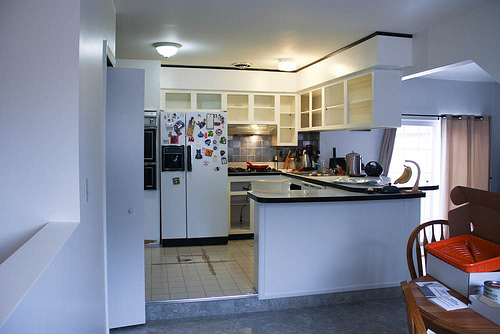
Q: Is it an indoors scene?
A: Yes, it is indoors.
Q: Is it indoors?
A: Yes, it is indoors.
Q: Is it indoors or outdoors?
A: It is indoors.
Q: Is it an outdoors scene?
A: No, it is indoors.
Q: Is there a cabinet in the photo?
A: Yes, there is a cabinet.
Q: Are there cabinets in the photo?
A: Yes, there is a cabinet.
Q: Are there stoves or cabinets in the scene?
A: Yes, there is a cabinet.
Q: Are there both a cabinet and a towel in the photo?
A: No, there is a cabinet but no towels.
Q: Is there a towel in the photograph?
A: No, there are no towels.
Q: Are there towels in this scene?
A: No, there are no towels.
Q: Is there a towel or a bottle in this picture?
A: No, there are no towels or bottles.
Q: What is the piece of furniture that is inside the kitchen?
A: The piece of furniture is a cabinet.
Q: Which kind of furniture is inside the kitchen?
A: The piece of furniture is a cabinet.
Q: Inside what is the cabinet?
A: The cabinet is inside the kitchen.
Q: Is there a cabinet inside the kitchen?
A: Yes, there is a cabinet inside the kitchen.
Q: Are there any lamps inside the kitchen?
A: No, there is a cabinet inside the kitchen.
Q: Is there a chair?
A: Yes, there is a chair.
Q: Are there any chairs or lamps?
A: Yes, there is a chair.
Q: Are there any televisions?
A: No, there are no televisions.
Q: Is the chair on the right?
A: Yes, the chair is on the right of the image.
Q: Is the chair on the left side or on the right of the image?
A: The chair is on the right of the image.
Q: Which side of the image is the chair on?
A: The chair is on the right of the image.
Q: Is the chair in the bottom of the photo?
A: Yes, the chair is in the bottom of the image.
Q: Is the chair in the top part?
A: No, the chair is in the bottom of the image.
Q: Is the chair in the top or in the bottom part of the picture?
A: The chair is in the bottom of the image.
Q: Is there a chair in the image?
A: Yes, there is a chair.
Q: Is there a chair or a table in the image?
A: Yes, there is a chair.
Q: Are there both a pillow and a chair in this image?
A: No, there is a chair but no pillows.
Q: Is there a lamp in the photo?
A: No, there are no lamps.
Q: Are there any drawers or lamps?
A: No, there are no lamps or drawers.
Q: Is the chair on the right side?
A: Yes, the chair is on the right of the image.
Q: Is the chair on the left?
A: No, the chair is on the right of the image.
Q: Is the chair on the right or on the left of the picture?
A: The chair is on the right of the image.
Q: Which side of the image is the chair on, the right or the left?
A: The chair is on the right of the image.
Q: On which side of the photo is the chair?
A: The chair is on the right of the image.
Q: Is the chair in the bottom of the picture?
A: Yes, the chair is in the bottom of the image.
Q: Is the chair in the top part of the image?
A: No, the chair is in the bottom of the image.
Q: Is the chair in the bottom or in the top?
A: The chair is in the bottom of the image.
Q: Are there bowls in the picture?
A: No, there are no bowls.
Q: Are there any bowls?
A: No, there are no bowls.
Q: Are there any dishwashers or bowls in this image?
A: No, there are no bowls or dishwashers.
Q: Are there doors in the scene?
A: Yes, there is a door.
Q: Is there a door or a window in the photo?
A: Yes, there is a door.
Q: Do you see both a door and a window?
A: Yes, there are both a door and a window.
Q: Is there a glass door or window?
A: Yes, there is a glass door.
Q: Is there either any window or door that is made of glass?
A: Yes, the door is made of glass.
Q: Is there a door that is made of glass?
A: Yes, there is a door that is made of glass.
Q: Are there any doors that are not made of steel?
A: Yes, there is a door that is made of glass.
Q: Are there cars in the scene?
A: No, there are no cars.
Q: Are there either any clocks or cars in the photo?
A: No, there are no cars or clocks.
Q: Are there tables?
A: Yes, there is a table.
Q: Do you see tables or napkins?
A: Yes, there is a table.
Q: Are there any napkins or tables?
A: Yes, there is a table.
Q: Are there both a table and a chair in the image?
A: Yes, there are both a table and a chair.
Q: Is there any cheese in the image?
A: No, there is no cheese.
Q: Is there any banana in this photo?
A: Yes, there are bananas.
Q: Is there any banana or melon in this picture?
A: Yes, there are bananas.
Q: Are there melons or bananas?
A: Yes, there are bananas.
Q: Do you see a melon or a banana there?
A: Yes, there are bananas.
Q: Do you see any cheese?
A: No, there is no cheese.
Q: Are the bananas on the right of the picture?
A: Yes, the bananas are on the right of the image.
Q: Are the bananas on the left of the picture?
A: No, the bananas are on the right of the image.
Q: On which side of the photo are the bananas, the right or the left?
A: The bananas are on the right of the image.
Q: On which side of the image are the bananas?
A: The bananas are on the right of the image.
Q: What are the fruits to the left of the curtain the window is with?
A: The fruits are bananas.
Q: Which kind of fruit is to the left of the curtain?
A: The fruits are bananas.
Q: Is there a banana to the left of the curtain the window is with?
A: Yes, there are bananas to the left of the curtain.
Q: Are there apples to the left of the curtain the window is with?
A: No, there are bananas to the left of the curtain.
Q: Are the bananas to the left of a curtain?
A: Yes, the bananas are to the left of a curtain.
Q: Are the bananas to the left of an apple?
A: No, the bananas are to the left of a curtain.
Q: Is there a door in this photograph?
A: Yes, there is a door.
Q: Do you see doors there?
A: Yes, there is a door.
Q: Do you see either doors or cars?
A: Yes, there is a door.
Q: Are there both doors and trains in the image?
A: No, there is a door but no trains.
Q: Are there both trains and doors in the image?
A: No, there is a door but no trains.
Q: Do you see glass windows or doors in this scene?
A: Yes, there is a glass door.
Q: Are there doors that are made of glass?
A: Yes, there is a door that is made of glass.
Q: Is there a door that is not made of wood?
A: Yes, there is a door that is made of glass.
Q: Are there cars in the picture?
A: No, there are no cars.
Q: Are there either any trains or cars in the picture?
A: No, there are no cars or trains.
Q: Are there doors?
A: Yes, there is a door.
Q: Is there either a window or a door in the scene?
A: Yes, there is a door.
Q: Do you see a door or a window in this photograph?
A: Yes, there is a door.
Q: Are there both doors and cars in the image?
A: No, there is a door but no cars.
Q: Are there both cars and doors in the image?
A: No, there is a door but no cars.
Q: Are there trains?
A: No, there are no trains.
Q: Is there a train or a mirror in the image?
A: No, there are no trains or mirrors.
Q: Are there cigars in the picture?
A: No, there are no cigars.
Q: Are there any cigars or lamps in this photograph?
A: No, there are no cigars or lamps.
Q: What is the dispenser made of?
A: The dispenser is made of plastic.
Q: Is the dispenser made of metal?
A: No, the dispenser is made of plastic.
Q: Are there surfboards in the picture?
A: No, there are no surfboards.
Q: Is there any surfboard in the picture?
A: No, there are no surfboards.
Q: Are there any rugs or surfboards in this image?
A: No, there are no surfboards or rugs.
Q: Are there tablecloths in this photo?
A: No, there are no tablecloths.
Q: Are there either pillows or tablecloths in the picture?
A: No, there are no tablecloths or pillows.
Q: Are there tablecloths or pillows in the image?
A: No, there are no tablecloths or pillows.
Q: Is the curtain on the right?
A: Yes, the curtain is on the right of the image.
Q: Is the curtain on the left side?
A: No, the curtain is on the right of the image.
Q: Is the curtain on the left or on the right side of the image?
A: The curtain is on the right of the image.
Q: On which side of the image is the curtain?
A: The curtain is on the right of the image.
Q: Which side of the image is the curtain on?
A: The curtain is on the right of the image.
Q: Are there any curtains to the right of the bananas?
A: Yes, there is a curtain to the right of the bananas.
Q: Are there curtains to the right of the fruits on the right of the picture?
A: Yes, there is a curtain to the right of the bananas.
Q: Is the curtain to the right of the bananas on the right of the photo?
A: Yes, the curtain is to the right of the bananas.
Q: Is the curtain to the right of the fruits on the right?
A: Yes, the curtain is to the right of the bananas.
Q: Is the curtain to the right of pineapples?
A: No, the curtain is to the right of the bananas.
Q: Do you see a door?
A: Yes, there is a door.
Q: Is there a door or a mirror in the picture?
A: Yes, there is a door.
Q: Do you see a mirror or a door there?
A: Yes, there is a door.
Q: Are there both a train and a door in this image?
A: No, there is a door but no trains.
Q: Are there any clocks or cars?
A: No, there are no cars or clocks.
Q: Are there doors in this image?
A: Yes, there is a door.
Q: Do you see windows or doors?
A: Yes, there is a door.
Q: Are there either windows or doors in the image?
A: Yes, there is a door.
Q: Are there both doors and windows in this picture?
A: Yes, there are both a door and a window.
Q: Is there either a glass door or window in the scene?
A: Yes, there is a glass door.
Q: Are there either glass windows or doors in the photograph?
A: Yes, there is a glass door.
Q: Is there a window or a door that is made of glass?
A: Yes, the door is made of glass.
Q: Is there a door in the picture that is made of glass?
A: Yes, there is a door that is made of glass.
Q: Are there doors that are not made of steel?
A: Yes, there is a door that is made of glass.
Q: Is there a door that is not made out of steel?
A: Yes, there is a door that is made of glass.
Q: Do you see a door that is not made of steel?
A: Yes, there is a door that is made of glass.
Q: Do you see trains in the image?
A: No, there are no trains.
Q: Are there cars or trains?
A: No, there are no trains or cars.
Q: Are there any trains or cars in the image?
A: No, there are no trains or cars.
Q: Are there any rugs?
A: No, there are no rugs.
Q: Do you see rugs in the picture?
A: No, there are no rugs.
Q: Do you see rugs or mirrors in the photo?
A: No, there are no rugs or mirrors.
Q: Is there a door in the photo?
A: Yes, there is a door.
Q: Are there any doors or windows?
A: Yes, there is a door.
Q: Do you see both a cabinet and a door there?
A: Yes, there are both a door and a cabinet.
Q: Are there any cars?
A: No, there are no cars.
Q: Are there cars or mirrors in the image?
A: No, there are no cars or mirrors.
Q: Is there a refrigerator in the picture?
A: Yes, there is a refrigerator.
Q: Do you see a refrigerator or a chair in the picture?
A: Yes, there is a refrigerator.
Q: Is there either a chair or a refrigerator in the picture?
A: Yes, there is a refrigerator.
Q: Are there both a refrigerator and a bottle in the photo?
A: No, there is a refrigerator but no bottles.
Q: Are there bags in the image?
A: No, there are no bags.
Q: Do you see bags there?
A: No, there are no bags.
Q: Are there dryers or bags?
A: No, there are no bags or dryers.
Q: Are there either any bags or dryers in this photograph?
A: No, there are no bags or dryers.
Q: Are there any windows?
A: Yes, there is a window.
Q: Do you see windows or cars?
A: Yes, there is a window.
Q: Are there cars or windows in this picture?
A: Yes, there is a window.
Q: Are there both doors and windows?
A: Yes, there are both a window and a door.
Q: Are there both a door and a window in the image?
A: Yes, there are both a window and a door.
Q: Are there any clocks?
A: No, there are no clocks.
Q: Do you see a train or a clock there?
A: No, there are no clocks or trains.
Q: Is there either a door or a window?
A: Yes, there is a door.